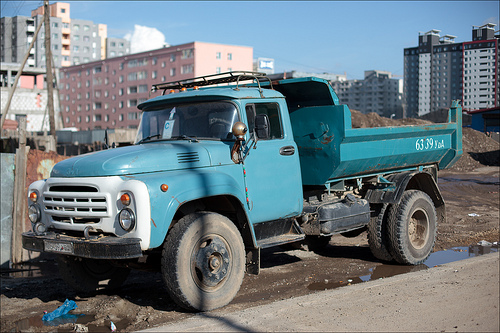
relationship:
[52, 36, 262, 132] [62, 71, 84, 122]
house has windows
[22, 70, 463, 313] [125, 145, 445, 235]
blue truck has side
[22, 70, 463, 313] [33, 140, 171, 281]
blue truck has front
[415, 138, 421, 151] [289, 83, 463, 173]
number on bed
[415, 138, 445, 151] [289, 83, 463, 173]
number on bed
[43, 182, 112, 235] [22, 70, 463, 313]
grill on blue truck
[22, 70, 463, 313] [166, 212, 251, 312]
blue truck has tire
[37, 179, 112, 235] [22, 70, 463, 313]
grill of blue truck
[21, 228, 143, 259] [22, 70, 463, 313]
bumper of blue truck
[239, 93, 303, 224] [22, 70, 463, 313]
door of blue truck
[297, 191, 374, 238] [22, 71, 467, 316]
gas tank on blue truck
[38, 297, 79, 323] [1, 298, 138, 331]
bag in puddle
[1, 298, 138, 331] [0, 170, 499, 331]
puddle on ground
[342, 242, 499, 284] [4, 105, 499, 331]
puddle in dirt